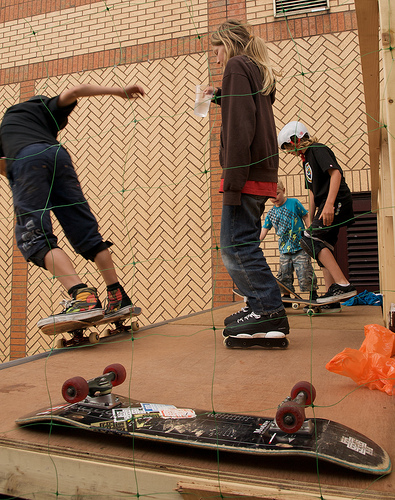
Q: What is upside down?
A: Skateboard.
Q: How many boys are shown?
A: Four.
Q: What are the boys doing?
A: Skateboarding.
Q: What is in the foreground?
A: A skateboard.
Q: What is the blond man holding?
A: Water.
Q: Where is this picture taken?
A: A skatepark.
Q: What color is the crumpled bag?
A: Orange.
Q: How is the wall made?
A: Of brick.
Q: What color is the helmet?
A: White.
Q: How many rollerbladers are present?
A: One.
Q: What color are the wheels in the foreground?
A: Red.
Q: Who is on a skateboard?
A: A boy.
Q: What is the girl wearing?
A: Brown sweatshirt.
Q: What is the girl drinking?
A: Water.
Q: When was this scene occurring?
A: Daytime.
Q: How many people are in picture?
A: 4.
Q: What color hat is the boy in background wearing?
A: White.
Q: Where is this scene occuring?
A: Skateboard park.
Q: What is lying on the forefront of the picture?
A: Skateboard.